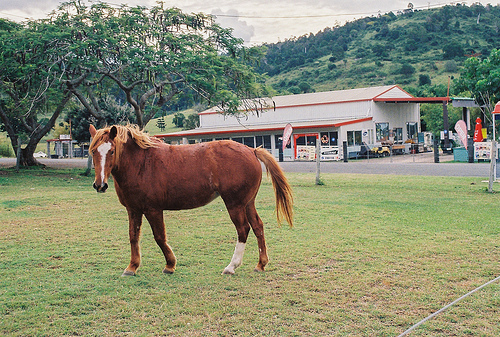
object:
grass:
[4, 167, 497, 335]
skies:
[367, 0, 499, 62]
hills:
[0, 0, 495, 133]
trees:
[87, 0, 260, 136]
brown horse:
[83, 120, 297, 278]